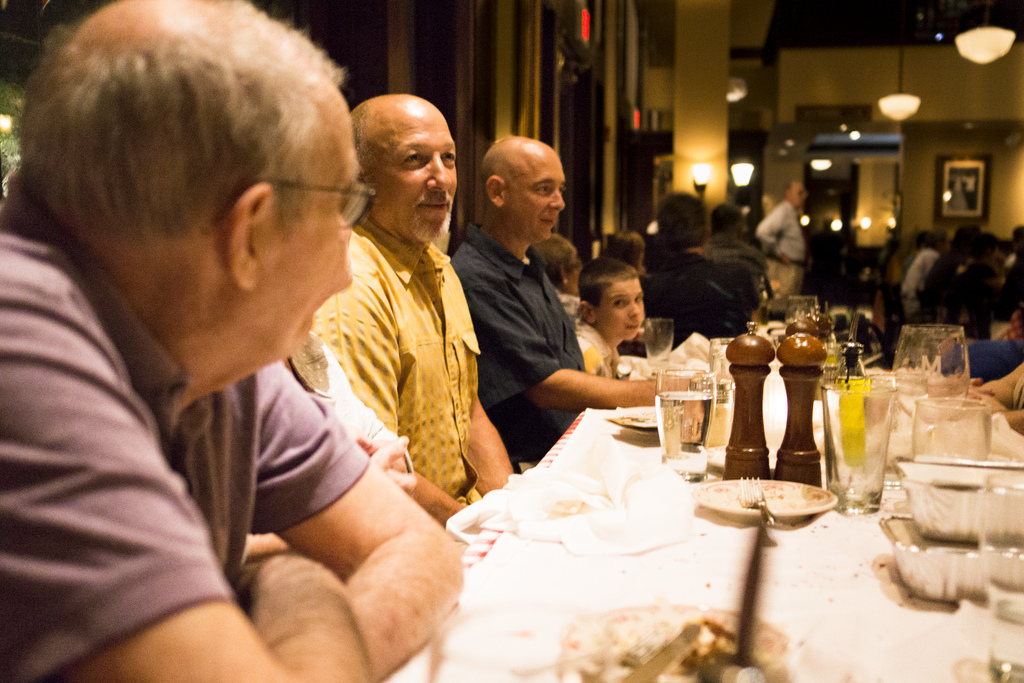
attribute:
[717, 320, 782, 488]
shaker — wooden 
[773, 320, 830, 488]
shaker — wooden 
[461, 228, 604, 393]
shirt — black 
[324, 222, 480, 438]
shirt — yellow 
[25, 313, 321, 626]
shirt — purple 